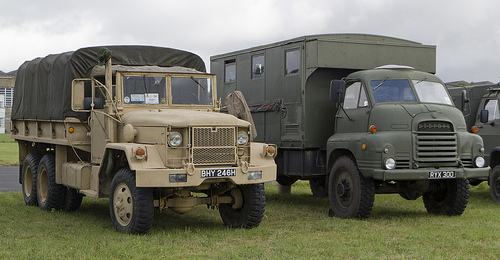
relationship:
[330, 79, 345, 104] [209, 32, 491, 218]
mirror on truck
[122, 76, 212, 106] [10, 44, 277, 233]
windshield on truck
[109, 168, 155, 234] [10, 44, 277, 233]
tire on truck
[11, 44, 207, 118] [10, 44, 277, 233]
tarp on truck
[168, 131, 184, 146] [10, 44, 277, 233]
headlight on truck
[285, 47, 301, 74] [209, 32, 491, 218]
window on truck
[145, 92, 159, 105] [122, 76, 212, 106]
paper in windshield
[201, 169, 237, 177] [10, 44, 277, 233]
license plate on truck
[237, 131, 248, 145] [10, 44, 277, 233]
headlight on truck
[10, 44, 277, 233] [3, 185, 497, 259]
truck in grass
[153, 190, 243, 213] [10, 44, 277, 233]
axle on truck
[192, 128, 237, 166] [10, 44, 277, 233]
grill on truck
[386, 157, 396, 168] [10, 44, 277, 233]
headlight on truck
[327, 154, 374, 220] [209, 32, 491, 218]
tire on truck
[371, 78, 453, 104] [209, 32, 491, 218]
windshield on truck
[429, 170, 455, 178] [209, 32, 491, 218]
license plate on truck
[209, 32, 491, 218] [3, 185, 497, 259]
truck on grass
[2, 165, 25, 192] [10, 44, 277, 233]
road behind truck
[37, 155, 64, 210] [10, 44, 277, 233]
tire on truck